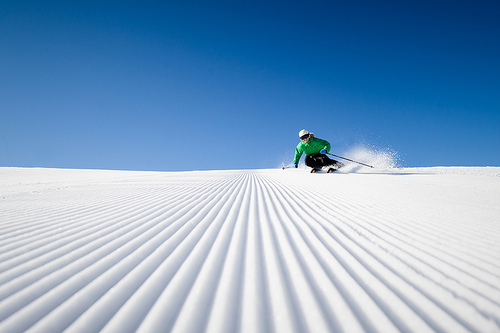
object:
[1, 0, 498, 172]
sky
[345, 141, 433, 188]
snow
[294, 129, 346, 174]
man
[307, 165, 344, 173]
skis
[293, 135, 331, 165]
green coat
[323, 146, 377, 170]
ski pole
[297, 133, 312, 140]
goggles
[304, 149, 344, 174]
pants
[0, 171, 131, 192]
snow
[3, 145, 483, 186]
horizon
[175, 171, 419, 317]
slope